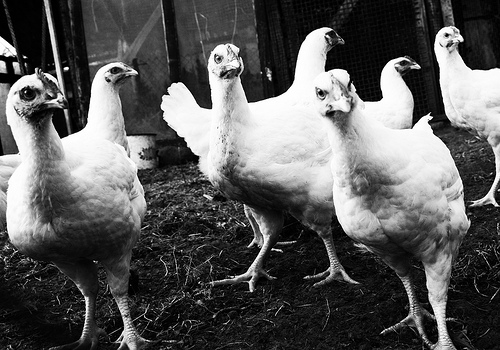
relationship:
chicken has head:
[6, 67, 149, 347] [7, 68, 75, 127]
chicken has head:
[311, 68, 471, 348] [309, 67, 360, 132]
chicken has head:
[207, 44, 362, 293] [204, 39, 246, 89]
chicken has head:
[433, 25, 498, 208] [432, 20, 464, 57]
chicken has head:
[346, 50, 423, 132] [376, 49, 422, 82]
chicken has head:
[207, 44, 362, 293] [305, 24, 349, 58]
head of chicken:
[315, 68, 359, 120] [311, 68, 471, 348]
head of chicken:
[7, 68, 75, 127] [6, 67, 149, 347]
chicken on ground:
[311, 68, 471, 348] [143, 197, 248, 330]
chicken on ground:
[6, 67, 152, 349] [131, 194, 379, 330]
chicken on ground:
[321, 67, 476, 343] [131, 194, 379, 330]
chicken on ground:
[428, 19, 495, 209] [131, 194, 379, 330]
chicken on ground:
[208, 36, 329, 217] [131, 194, 379, 330]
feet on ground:
[211, 227, 361, 297] [19, 122, 499, 349]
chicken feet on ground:
[62, 327, 185, 348] [19, 122, 499, 349]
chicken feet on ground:
[204, 265, 361, 291] [19, 122, 499, 349]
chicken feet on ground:
[376, 304, 465, 348] [19, 122, 499, 349]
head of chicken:
[16, 68, 66, 130] [6, 67, 149, 347]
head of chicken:
[84, 53, 141, 99] [6, 67, 152, 349]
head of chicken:
[208, 25, 252, 95] [194, 41, 366, 294]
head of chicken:
[436, 10, 463, 64] [428, 19, 495, 209]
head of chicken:
[378, 55, 423, 77] [351, 55, 421, 132]